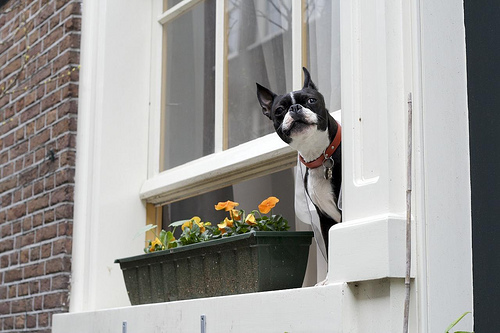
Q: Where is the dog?
A: Partially out of window.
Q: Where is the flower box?
A: Front of dog.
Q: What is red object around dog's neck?
A: Collar.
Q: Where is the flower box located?
A: Window sill.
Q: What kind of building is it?
A: Brick.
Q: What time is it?
A: Afternoon.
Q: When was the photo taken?
A: During the daytime.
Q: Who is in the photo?
A: No people.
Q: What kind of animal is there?
A: Dog.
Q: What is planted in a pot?
A: Flowers.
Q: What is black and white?
A: The dog.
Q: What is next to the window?
A: Bricks.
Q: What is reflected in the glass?
A: Trees.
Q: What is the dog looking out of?
A: A window.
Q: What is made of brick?
A: The building.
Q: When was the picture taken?
A: Daytime.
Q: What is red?
A: Collar.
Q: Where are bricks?
A: On a building.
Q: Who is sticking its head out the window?
A: A dog.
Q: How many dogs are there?
A: One.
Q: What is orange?
A: Flowers.